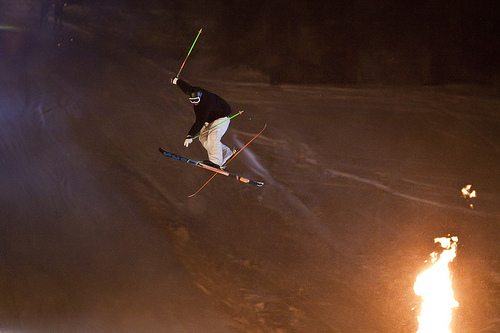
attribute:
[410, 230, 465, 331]
fire — large, orange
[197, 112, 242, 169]
pants — tan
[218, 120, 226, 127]
ski pole — green and orange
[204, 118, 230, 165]
leg — long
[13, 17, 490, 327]
snow — white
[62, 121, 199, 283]
snow — white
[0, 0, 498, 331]
snow — white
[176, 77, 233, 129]
shirt — black, long sleeved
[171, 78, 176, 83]
glove — white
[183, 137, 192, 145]
glove — white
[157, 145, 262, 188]
ski — long, red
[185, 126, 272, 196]
ski — long, red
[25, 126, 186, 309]
snow — white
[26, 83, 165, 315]
snow — white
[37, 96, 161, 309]
snow — white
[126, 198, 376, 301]
snow — white